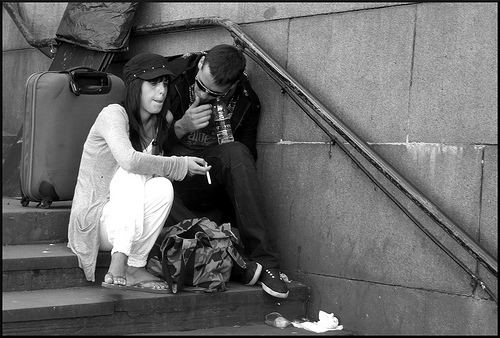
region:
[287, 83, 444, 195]
rail leading up the stairs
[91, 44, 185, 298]
girl in white pants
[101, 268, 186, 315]
girl wearing flip flops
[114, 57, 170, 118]
girl wearing black hat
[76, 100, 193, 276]
girl wearing long sleeved shirt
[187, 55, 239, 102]
guy wearing sun glasses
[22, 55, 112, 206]
rolling suitcase with black handle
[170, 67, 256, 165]
guy with hand to face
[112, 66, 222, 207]
girl holding cigarette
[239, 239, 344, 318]
guy wearing dark shoes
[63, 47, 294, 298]
two people sit on the stairs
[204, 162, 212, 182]
the girl smokes a cig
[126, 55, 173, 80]
the girl wears a hat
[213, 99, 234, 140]
the man has a bottle of water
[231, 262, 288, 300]
the man is wearing sneakers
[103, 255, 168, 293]
the woman is wearing flip flips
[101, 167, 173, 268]
the woman wears white pants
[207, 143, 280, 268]
the man wears denim pants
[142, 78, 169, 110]
the woman is looking down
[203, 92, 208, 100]
the man touches his nose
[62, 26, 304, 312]
a man and woman sitting on steps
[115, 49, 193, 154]
a woman wearing a hat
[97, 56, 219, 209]
a woman holding a cigarette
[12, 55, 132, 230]
a suitcase sitting on a step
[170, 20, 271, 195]
a man wearing sunglasses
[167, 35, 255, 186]
a man with a water bottle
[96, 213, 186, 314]
a woman wearing flip flops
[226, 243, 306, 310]
shoes with o shoe laces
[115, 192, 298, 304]
a bag sitting on a step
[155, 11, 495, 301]
a handrail on the wall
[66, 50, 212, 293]
Young lady sitting on steps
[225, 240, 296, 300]
Black and white tennis shoes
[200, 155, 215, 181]
Cigarette in young lady's right hand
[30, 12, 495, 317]
Banister attached to wall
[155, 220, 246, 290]
Bag sitting on steps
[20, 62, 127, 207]
Suitcase with wheels sitting on landing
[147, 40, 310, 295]
Young man sitting on steps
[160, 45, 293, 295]
Man holding water bottle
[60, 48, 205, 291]
Woman wearing flip flops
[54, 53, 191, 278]
Sweater young woman is wearing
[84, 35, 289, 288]
a couple sitting on some stairs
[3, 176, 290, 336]
a set of stairs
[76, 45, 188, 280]
a young woman sitting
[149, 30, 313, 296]
a young man sitting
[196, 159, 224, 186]
cigarette in the woman's hand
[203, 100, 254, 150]
a bottle on the man's leg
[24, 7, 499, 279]
some hand railing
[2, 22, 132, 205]
Some luggage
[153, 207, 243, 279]
a bag in between the couple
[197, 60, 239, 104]
sunglasses on the man's head